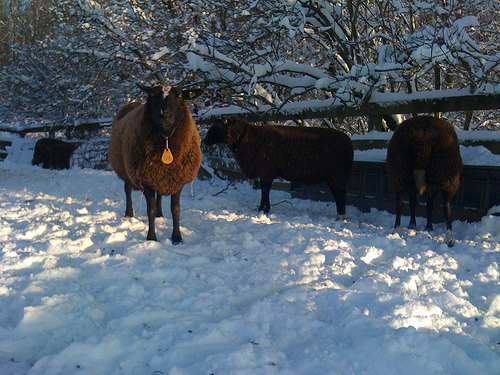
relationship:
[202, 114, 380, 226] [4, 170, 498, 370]
sheep in snow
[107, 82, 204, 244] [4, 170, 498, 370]
sheep in snow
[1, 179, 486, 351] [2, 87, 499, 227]
snow covering fence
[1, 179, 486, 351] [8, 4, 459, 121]
snow covering tree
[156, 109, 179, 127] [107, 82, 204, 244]
nose of sheep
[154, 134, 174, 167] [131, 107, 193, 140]
collar around neck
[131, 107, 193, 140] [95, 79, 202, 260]
neck of sheep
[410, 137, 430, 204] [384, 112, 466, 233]
tail of sheep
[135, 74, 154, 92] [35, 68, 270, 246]
ear of sheep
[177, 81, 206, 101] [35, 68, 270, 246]
ear of sheep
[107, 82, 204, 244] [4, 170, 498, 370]
sheep standing in snow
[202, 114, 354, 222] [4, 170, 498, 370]
sheep standing in snow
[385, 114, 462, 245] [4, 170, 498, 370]
sheep standing in snow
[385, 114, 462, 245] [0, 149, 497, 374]
sheep standing in snow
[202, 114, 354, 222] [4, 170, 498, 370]
sheep in snow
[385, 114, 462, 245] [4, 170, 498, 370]
sheep in snow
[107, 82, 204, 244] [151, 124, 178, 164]
sheep wearing a tag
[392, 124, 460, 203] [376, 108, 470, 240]
backside of a sheep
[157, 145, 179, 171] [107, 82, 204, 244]
tag on sheep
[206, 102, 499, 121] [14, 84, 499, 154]
railing on fence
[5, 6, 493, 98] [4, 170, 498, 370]
trees covered with snow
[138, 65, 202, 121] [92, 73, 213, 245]
antlers on reindeer